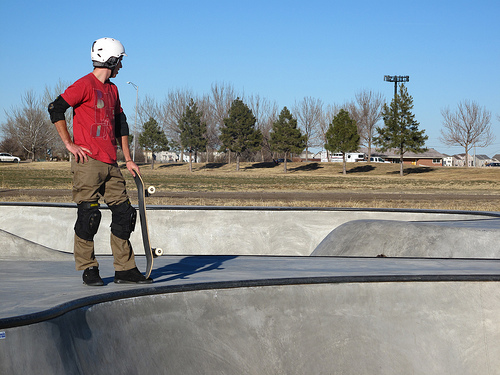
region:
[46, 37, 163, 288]
A kid with a skateboard.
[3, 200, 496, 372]
A cement skate park.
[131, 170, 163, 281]
A skateboard standing up.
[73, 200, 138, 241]
Two black knee pads.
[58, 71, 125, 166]
A kids orange t shirt.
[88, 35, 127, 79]
a white safety helmet.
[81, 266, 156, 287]
A pair of black shoes.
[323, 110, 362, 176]
A green pine tree.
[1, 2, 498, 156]
A clear blue sky.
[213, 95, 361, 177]
Three green pine trees.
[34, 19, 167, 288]
skateboarder standing on top of a ramp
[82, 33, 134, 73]
helmet of a skateboarder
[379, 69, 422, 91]
lights on a pole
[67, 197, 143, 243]
knee pads of a skateboarder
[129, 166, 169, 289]
black skateboard resting in man's hand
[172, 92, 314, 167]
three green trees in the background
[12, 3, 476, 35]
blue sky in the distance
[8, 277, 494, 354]
skateboarding ramp in a park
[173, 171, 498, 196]
brown and green grassy area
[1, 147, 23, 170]
car parked in the background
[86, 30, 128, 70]
a white helmet on the man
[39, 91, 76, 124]
a black elbow pad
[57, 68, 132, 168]
a red tee shirt on the man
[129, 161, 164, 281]
a black skateboard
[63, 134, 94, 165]
the hand of a man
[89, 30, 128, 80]
the head of a man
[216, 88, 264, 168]
a green tree on the grass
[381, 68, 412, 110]
a large light post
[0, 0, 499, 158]
a clear blue sky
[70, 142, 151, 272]
a pair of brown pants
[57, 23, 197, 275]
a man standing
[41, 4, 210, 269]
a man wearing a white helmet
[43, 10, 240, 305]
man at skate park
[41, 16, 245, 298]
man holding a skateboard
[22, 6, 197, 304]
a man wearing knee pads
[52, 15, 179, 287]
man wearing elbow pads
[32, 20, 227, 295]
man wearing khakis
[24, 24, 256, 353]
a man during the day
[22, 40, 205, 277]
a man with a red shirt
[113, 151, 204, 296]
a black skate board with white wheels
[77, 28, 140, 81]
Man wearing white helmet.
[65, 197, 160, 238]
Man wearing black knee pads.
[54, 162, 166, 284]
Man wearing tan pants.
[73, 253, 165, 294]
Man wearing black shoes.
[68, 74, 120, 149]
Man wearing read shirt.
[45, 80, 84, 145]
Man wearing black elbow pads.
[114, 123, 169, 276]
Man holding black skateboard.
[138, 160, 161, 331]
Skateboard has white wheels.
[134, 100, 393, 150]
Trees have green leaves.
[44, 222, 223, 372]
Man standing on concrete.